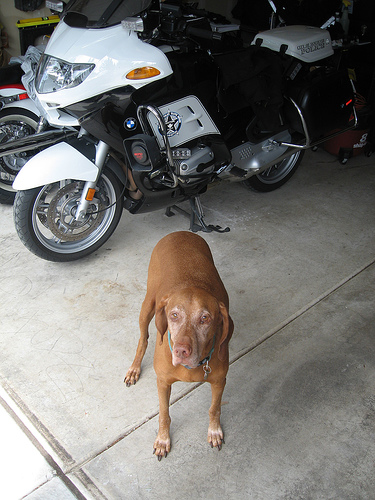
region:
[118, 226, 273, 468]
short haired brown dog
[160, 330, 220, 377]
blue collar wrapped around the neck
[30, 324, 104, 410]
thin marks in the cement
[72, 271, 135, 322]
brown spot on the ground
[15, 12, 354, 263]
parked motorcycle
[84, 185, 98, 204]
orange reflectr on the bottom wheel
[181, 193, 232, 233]
kickstand is down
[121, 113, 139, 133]
blue and white logo on the bike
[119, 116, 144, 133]
small BMW logo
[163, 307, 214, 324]
two tiny eyes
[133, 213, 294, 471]
the dog is brown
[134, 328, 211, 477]
the dog is brown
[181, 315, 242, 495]
the dog is brown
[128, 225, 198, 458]
the dog is brown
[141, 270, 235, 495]
the dog is brown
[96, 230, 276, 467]
dog standing on the concrete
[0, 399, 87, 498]
strip of black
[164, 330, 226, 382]
blue collar around the neck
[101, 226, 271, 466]
brown short haired dog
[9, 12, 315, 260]
motorcycle parked on the concrete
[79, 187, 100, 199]
orange reflector on the front wheel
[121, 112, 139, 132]
small blue and white logo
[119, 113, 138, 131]
BMW logo on the side of the bike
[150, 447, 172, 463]
long black nails on the paw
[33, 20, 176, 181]
the motor is white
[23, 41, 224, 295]
the motor is white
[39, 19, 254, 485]
the motor is white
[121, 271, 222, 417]
the dog is brown